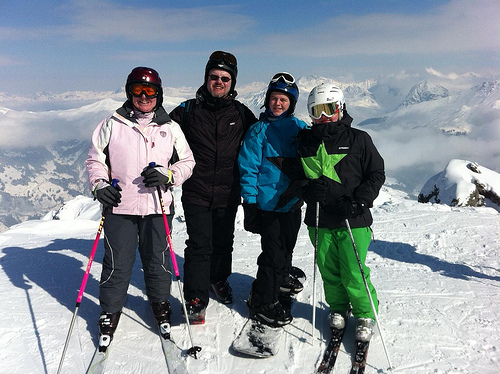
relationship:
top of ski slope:
[4, 46, 490, 372] [379, 194, 498, 372]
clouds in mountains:
[361, 120, 491, 200] [1, 57, 498, 222]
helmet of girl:
[271, 70, 301, 96] [260, 62, 314, 299]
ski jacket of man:
[166, 88, 260, 211] [188, 55, 256, 312]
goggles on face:
[130, 87, 160, 99] [128, 81, 158, 111]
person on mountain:
[83, 64, 197, 352] [408, 181, 495, 370]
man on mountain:
[169, 50, 254, 324] [408, 181, 495, 370]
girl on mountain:
[238, 71, 309, 326] [408, 181, 495, 370]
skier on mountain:
[292, 74, 387, 372] [408, 181, 495, 370]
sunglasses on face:
[207, 72, 234, 86] [206, 62, 235, 99]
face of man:
[206, 62, 235, 99] [169, 48, 254, 324]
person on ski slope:
[86, 61, 198, 366] [4, 163, 482, 372]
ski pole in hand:
[156, 183, 203, 360] [139, 161, 169, 191]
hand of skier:
[139, 161, 169, 191] [82, 65, 199, 352]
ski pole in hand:
[311, 197, 318, 362] [301, 170, 328, 208]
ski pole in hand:
[344, 218, 398, 372] [332, 191, 364, 227]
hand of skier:
[332, 191, 364, 227] [281, 79, 391, 372]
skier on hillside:
[292, 82, 387, 344] [1, 190, 498, 370]